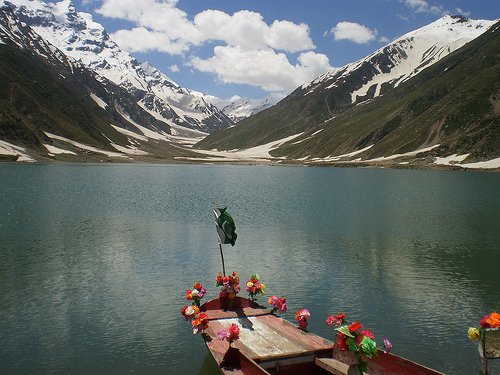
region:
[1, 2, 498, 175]
valley between snow capped mountains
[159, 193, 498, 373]
painted wooden boat in a lake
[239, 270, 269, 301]
bouquet of multi colored flowers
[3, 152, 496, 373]
deep turquoise coloured lake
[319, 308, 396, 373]
bouquet of multi colored flowers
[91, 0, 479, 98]
big puffy white clouds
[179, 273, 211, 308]
bouquet of multi colored flowers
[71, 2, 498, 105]
blue sky with several clouds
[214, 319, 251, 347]
bouquet of multi colored flowers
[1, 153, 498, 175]
shore line of the lake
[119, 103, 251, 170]
a valley in the mountains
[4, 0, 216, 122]
a snowcovered cliff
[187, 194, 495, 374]
a boat in the water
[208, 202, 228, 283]
a pole on the boat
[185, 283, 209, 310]
a bouquet on the boat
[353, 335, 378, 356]
a green flower in a bouquet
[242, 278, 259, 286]
a yellow flower in the bouquet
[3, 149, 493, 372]
the water is greenish blue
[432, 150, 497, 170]
a patch of snow on the mountain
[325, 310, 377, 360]
Red flowers and green leaves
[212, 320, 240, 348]
Red and pink flower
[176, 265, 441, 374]
Wood boat with flowers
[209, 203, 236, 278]
Fish flag on a pole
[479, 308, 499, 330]
Red and orange flowers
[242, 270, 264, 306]
Bouquet of flowers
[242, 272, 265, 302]
Yellow and red flowers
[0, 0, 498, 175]
Large mountain range with snow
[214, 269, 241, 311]
Bouquet of flowers at the end of a boat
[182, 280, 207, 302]
Purple, red and white bouquet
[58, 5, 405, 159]
A valley between snow capped mountains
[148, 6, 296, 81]
Cumulus clouds against a vibrant blue sky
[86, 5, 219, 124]
Fluffy cumulus clouds over a snow capped mountain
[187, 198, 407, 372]
Tip of a canue decorated with multi-colored flowers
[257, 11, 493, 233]
Part of a lake leading into base of a mountain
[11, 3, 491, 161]
Pair of mountains with a valley inbetween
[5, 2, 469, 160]
A valley inbetween two mountains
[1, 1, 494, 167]
A valley inbetween two snow capped mountains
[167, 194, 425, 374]
Part of a decorated canoe on a lake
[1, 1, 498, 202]
A Bob Ross painting in real life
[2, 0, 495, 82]
mountains covered with snow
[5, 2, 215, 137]
the mountains are rocky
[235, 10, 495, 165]
the mountains are rocky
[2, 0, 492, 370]
a lake in front the mountains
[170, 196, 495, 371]
a boat is color red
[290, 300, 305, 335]
red and pink flowers on boat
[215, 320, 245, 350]
red and pink flowers on boat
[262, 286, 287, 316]
red and pink flowers on boat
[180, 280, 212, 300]
red, white and pink flowers on boat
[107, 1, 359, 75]
white clouds on a blue sky